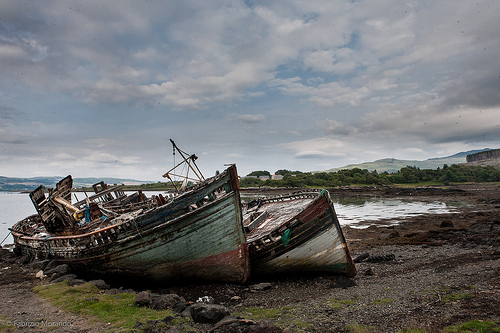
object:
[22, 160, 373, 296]
boats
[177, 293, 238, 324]
rock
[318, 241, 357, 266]
mark